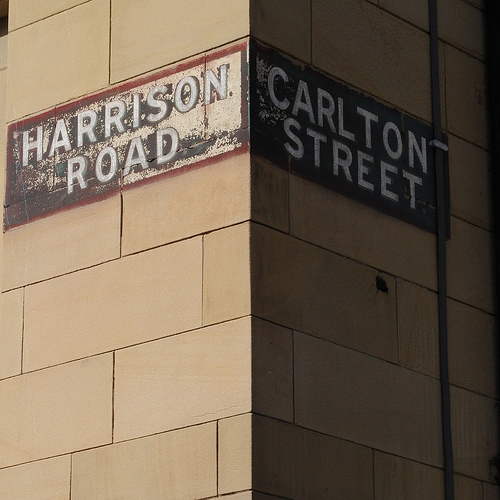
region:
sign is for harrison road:
[11, 63, 220, 201]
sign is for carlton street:
[242, 60, 438, 225]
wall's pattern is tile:
[80, 328, 252, 438]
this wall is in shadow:
[255, 419, 390, 495]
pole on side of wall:
[402, 235, 498, 420]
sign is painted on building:
[2, 85, 231, 174]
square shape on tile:
[99, 326, 252, 431]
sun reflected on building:
[35, 333, 206, 492]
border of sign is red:
[184, 139, 249, 164]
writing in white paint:
[88, 120, 184, 186]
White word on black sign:
[62, 125, 177, 192]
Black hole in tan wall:
[372, 270, 388, 295]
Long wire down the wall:
[427, 0, 450, 497]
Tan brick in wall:
[1, 350, 115, 443]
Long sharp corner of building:
[250, 1, 252, 498]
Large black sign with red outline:
[4, 34, 453, 236]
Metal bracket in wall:
[427, 138, 449, 150]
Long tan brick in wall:
[293, 328, 496, 487]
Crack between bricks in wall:
[209, 419, 221, 496]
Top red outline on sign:
[2, 27, 252, 127]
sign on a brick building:
[7, 66, 249, 238]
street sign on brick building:
[247, 32, 479, 234]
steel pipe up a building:
[413, 12, 480, 496]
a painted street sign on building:
[237, 35, 492, 250]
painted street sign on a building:
[0, 46, 255, 224]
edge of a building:
[213, 153, 300, 498]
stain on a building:
[367, 265, 402, 296]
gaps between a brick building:
[113, 189, 131, 261]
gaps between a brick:
[103, 341, 128, 448]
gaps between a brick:
[275, 318, 309, 425]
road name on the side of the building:
[6, 79, 245, 226]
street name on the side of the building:
[251, 40, 482, 257]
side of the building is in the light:
[56, 198, 214, 438]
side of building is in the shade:
[247, 231, 414, 438]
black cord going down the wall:
[416, 32, 471, 396]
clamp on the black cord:
[431, 133, 452, 158]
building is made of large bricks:
[25, 221, 219, 485]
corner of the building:
[196, 248, 297, 479]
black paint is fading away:
[186, 98, 248, 169]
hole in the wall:
[366, 270, 398, 307]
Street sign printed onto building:
[0, 38, 250, 235]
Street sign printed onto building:
[249, 38, 450, 226]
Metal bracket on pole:
[430, 138, 449, 150]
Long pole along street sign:
[427, 0, 455, 499]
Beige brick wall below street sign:
[19, 232, 203, 376]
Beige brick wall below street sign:
[0, 348, 114, 470]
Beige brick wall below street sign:
[0, 195, 121, 295]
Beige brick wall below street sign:
[250, 222, 397, 361]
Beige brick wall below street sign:
[292, 329, 441, 465]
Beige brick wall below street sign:
[287, 171, 437, 290]